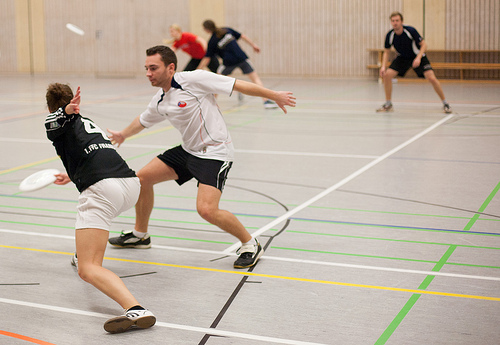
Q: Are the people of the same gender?
A: No, they are both male and female.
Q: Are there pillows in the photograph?
A: No, there are no pillows.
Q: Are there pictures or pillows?
A: No, there are no pillows or pictures.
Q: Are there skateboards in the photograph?
A: No, there are no skateboards.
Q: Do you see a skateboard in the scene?
A: No, there are no skateboards.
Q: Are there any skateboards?
A: No, there are no skateboards.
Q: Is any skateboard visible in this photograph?
A: No, there are no skateboards.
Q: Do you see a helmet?
A: No, there are no helmets.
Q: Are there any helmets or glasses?
A: No, there are no helmets or glasses.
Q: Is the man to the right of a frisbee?
A: Yes, the man is to the right of a frisbee.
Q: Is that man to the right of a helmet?
A: No, the man is to the right of a frisbee.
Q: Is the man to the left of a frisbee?
A: No, the man is to the right of a frisbee.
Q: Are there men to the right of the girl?
A: Yes, there is a man to the right of the girl.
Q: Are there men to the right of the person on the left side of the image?
A: Yes, there is a man to the right of the girl.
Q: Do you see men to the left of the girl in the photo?
A: No, the man is to the right of the girl.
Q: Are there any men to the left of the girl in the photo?
A: No, the man is to the right of the girl.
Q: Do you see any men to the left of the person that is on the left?
A: No, the man is to the right of the girl.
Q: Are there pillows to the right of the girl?
A: No, there is a man to the right of the girl.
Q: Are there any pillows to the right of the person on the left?
A: No, there is a man to the right of the girl.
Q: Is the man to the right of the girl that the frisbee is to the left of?
A: Yes, the man is to the right of the girl.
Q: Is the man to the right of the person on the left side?
A: Yes, the man is to the right of the girl.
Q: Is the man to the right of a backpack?
A: No, the man is to the right of the girl.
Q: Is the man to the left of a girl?
A: No, the man is to the right of a girl.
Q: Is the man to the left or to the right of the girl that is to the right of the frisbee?
A: The man is to the right of the girl.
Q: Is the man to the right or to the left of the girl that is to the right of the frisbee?
A: The man is to the right of the girl.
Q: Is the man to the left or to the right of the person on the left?
A: The man is to the right of the girl.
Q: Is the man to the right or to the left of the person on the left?
A: The man is to the right of the girl.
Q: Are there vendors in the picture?
A: No, there are no vendors.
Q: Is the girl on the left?
A: Yes, the girl is on the left of the image.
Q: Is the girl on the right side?
A: No, the girl is on the left of the image.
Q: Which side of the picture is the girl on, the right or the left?
A: The girl is on the left of the image.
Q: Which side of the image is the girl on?
A: The girl is on the left of the image.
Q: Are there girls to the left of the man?
A: Yes, there is a girl to the left of the man.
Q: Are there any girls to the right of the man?
A: No, the girl is to the left of the man.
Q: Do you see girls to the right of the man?
A: No, the girl is to the left of the man.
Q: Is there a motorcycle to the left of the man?
A: No, there is a girl to the left of the man.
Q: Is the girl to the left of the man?
A: Yes, the girl is to the left of the man.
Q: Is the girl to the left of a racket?
A: No, the girl is to the left of the man.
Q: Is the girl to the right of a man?
A: No, the girl is to the left of a man.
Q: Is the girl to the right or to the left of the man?
A: The girl is to the left of the man.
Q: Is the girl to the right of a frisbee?
A: Yes, the girl is to the right of a frisbee.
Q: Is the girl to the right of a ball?
A: No, the girl is to the right of a frisbee.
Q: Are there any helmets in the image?
A: No, there are no helmets.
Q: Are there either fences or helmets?
A: No, there are no helmets or fences.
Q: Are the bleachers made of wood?
A: Yes, the bleachers are made of wood.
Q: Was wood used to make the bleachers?
A: Yes, the bleachers are made of wood.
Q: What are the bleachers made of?
A: The bleachers are made of wood.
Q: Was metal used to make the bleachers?
A: No, the bleachers are made of wood.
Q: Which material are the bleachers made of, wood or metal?
A: The bleachers are made of wood.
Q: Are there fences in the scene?
A: No, there are no fences.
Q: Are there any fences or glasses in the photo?
A: No, there are no fences or glasses.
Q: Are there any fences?
A: No, there are no fences.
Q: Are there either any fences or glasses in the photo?
A: No, there are no fences or glasses.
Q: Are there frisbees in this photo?
A: Yes, there is a frisbee.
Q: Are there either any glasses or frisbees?
A: Yes, there is a frisbee.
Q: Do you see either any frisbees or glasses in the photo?
A: Yes, there is a frisbee.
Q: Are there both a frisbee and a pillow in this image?
A: No, there is a frisbee but no pillows.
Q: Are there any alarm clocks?
A: No, there are no alarm clocks.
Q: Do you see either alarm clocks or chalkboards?
A: No, there are no alarm clocks or chalkboards.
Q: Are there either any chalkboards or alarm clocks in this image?
A: No, there are no alarm clocks or chalkboards.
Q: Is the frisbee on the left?
A: Yes, the frisbee is on the left of the image.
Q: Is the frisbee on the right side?
A: No, the frisbee is on the left of the image.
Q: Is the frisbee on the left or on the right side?
A: The frisbee is on the left of the image.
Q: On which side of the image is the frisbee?
A: The frisbee is on the left of the image.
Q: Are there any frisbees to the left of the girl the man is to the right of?
A: Yes, there is a frisbee to the left of the girl.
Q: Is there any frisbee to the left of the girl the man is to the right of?
A: Yes, there is a frisbee to the left of the girl.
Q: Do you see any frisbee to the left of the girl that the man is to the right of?
A: Yes, there is a frisbee to the left of the girl.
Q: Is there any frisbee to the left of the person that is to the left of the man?
A: Yes, there is a frisbee to the left of the girl.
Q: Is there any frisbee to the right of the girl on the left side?
A: No, the frisbee is to the left of the girl.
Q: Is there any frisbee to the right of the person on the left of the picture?
A: No, the frisbee is to the left of the girl.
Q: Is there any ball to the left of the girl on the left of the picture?
A: No, there is a frisbee to the left of the girl.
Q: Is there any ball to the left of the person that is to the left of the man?
A: No, there is a frisbee to the left of the girl.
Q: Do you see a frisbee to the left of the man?
A: Yes, there is a frisbee to the left of the man.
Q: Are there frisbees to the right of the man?
A: No, the frisbee is to the left of the man.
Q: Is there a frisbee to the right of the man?
A: No, the frisbee is to the left of the man.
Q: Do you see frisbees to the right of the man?
A: No, the frisbee is to the left of the man.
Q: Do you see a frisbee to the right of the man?
A: No, the frisbee is to the left of the man.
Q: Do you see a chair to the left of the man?
A: No, there is a frisbee to the left of the man.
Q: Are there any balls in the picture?
A: No, there are no balls.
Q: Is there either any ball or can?
A: No, there are no balls or cans.